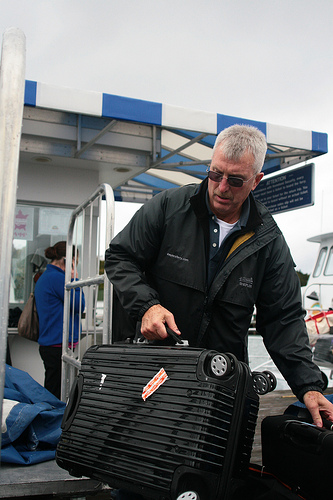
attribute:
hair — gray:
[199, 118, 260, 176]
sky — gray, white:
[94, 41, 289, 88]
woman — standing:
[27, 228, 78, 390]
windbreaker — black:
[99, 178, 274, 401]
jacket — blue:
[23, 259, 122, 389]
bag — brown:
[10, 262, 37, 347]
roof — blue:
[25, 69, 207, 142]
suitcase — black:
[34, 338, 262, 491]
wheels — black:
[184, 350, 274, 405]